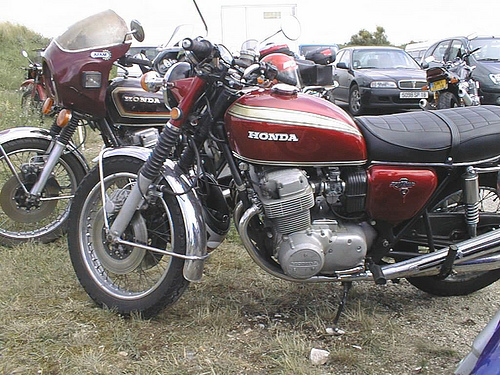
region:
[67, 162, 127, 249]
tire on a cycle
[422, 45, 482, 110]
cycle near a car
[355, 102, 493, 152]
seat on a cycle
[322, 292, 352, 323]
kick stand on a cycle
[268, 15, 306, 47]
mirror on a cycle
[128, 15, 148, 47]
mirror on a cycle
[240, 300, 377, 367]
rocks in the grass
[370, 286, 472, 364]
the rocks are gray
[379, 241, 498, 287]
the pipe is chrome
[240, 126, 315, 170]
the brand is on motorcycle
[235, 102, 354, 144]
the stripe is tan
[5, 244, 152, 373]
the grass is dry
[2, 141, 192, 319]
the wheels in the grass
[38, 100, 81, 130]
the lights are orange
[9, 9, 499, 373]
a couple of bikes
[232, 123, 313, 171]
the word HONDA on a bike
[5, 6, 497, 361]
a couple of vehicles in the parking lot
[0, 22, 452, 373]
green grass in the area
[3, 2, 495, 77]
a white sky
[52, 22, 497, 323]
a red bike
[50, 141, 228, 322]
a black wheel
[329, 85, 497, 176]
a black seat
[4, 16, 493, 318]
two parked motorcycles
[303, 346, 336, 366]
a rock on the ground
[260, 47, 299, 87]
a red helmet with a face shield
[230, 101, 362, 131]
a gold stripe on a motorcycle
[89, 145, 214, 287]
a chrome fender on a motorcycle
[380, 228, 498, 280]
a chrome muffler on a motorcycle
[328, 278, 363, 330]
a kick stand on a motorcycle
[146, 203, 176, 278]
spokes on a wheel of a motorcycle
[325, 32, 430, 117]
a parked car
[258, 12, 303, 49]
a rear view mirror on a motorcycle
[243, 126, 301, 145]
"HONDA" written on a motorbike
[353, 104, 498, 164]
A black leather seat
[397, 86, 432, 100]
A white license plate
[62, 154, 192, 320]
A round black tire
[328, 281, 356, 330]
The kickstand is down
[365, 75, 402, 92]
One headlight of a car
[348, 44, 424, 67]
Front window of the car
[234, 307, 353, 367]
Rocks on the grass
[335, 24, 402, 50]
Green leaves on a tree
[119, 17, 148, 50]
Round mirror of a motorbike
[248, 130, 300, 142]
word HONDA is in white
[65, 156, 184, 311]
motorcycle has a black wheel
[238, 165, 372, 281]
the motor of the motorcycle is a gray color